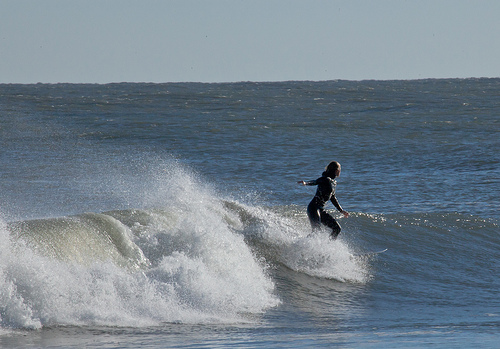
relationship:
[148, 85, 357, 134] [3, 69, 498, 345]
ripples in water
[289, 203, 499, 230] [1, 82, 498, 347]
ripples in ocean water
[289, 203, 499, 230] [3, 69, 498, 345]
ripples in water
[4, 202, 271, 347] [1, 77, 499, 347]
crashing waves in ocean water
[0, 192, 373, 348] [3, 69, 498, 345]
crashing waves crashing in water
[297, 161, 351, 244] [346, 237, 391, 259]
woman riding a surfboard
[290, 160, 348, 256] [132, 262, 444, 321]
woman surfing on water